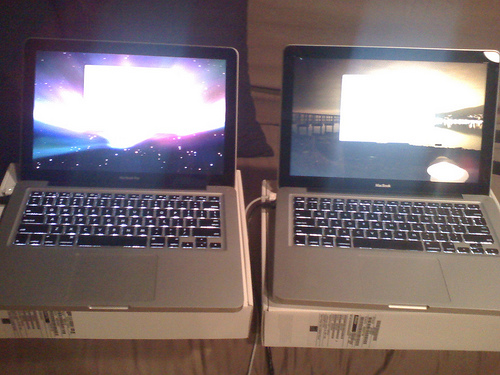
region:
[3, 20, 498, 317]
Two laptops sitting side by side.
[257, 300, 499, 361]
White box under the laptop.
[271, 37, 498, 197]
Computer monitor is on and visible.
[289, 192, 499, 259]
Black keyboard that is illuminated underneath.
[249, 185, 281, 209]
Power cord plugged into the computer.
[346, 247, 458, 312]
Computer track pad on the laptop.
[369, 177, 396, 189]
Name of the laptop manufacturer.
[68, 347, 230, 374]
Wood paneling on the cabinet below the laptops.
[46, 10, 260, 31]
Dark colored pillow propped up.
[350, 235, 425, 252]
Lont rectangular space bar.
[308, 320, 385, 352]
Sticker on a box.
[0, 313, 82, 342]
Sticker on the box.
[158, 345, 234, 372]
The table is wooden.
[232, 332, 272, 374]
The cord is white.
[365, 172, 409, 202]
Brand on the computer.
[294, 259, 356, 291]
Bottom of the computer is grey.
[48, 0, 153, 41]
Pillow in the background.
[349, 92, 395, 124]
White on the screen.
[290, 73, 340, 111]
Grey on the screen.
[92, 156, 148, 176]
Black on the screen.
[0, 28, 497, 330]
These are two laptops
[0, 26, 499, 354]
These two laptops are on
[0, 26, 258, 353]
This laptop is on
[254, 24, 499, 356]
This laptop is on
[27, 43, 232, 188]
This is the display of a laptop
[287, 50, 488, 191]
This is the display of a laptop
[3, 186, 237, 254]
This is the keyboard of a laptop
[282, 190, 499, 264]
This is the keyboard of a laptop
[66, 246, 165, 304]
This is the mousepad of a laptop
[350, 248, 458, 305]
This is the mousepad of a laptop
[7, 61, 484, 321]
Two Apple laptops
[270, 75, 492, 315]
MacBook Pro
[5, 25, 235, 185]
Laptop screen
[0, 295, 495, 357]
white boxes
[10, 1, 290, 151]
Burgundy pillow behind the computer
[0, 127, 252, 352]
computer sits on top of box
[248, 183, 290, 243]
Wire plugged into a usb port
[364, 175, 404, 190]
Logo for MacBook pro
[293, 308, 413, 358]
Information about the computer on the box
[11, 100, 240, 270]
Lit screen and keys are backlit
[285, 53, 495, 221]
Illuminated laptop screen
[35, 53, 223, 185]
Illuminated laptop screen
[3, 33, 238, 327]
Silver and black laptop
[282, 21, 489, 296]
Silver and black laptop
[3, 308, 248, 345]
White cardboard box under laptop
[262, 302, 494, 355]
White cardboard box under computer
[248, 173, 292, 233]
White USB cord in computer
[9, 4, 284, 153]
Dark towel behind laptop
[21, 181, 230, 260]
Black illuminated keys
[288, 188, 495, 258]
Black illuminated keys on laptop